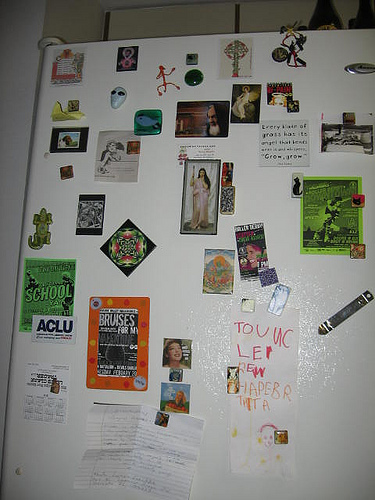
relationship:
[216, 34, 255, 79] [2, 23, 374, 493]
cross on refrigerator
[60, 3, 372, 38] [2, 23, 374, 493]
cabinetry above refrigerator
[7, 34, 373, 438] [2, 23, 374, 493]
magnets on refrigerator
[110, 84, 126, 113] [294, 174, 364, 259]
magnet on flyer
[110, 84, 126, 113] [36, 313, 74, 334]
magnet says aclu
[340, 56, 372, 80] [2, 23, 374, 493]
label on refrigerator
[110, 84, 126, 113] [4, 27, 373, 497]
magnet on fridge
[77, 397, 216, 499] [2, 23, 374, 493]
school work on refrigerator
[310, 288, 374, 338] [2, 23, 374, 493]
can opener on refrigerator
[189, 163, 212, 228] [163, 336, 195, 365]
woman in picture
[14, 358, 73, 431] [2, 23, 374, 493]
calendar front refrigerator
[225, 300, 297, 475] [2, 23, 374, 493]
drawing front refrigerator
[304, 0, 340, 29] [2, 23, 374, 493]
bottle on refrigerator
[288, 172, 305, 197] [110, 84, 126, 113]
cat on magnet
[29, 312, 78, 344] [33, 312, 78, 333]
sticker says aclu